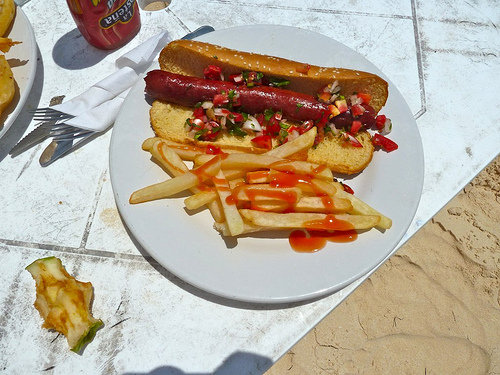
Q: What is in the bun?
A: A hot dog.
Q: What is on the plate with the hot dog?
A: French Fries.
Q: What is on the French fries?
A: Ketchup.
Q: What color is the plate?
A: White.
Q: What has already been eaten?
A: An apple.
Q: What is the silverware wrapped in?
A: Napkins.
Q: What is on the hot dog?
A: Relish.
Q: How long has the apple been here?
A: More than an hour.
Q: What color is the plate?
A: White.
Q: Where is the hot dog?
A: On the plate.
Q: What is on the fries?
A: Ketchup.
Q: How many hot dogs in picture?
A: One.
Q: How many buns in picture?
A: One.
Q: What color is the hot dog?
A: Red.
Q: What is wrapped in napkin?
A: Silverware.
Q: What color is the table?
A: White.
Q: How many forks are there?
A: Two.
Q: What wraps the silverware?
A: Napkins.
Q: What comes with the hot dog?
A: Fries.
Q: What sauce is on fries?
A: Ketchup.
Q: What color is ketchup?
A: Red.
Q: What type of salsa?
A: Pico de gallo.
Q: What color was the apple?
A: Green.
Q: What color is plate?
A: White.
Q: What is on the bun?
A: Hot Dog.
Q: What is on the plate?
A: Food.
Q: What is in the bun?
A: A hot dog.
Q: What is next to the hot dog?
A: French fries.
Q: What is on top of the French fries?
A: Ketchup.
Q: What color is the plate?
A: White.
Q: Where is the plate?
A: On a table.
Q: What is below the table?
A: Sand.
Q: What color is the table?
A: White.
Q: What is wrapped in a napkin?
A: Silverware.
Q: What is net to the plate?
A: An apple core.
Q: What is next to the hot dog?
A: Fries.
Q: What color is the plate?
A: White.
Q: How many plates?
A: 2.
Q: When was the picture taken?
A: Daytime.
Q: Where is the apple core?
A: Beside the plate.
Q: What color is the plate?
A: White.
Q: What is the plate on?
A: A table.